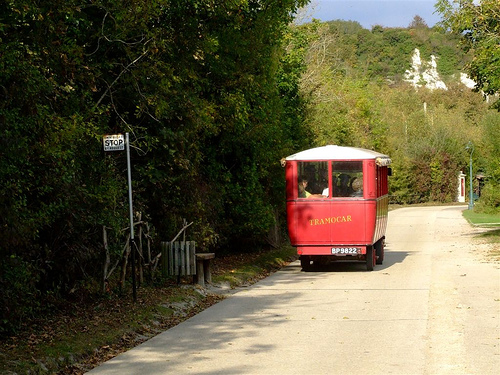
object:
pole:
[465, 136, 477, 213]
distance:
[273, 6, 498, 248]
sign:
[104, 131, 129, 152]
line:
[225, 291, 438, 333]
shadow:
[300, 247, 418, 278]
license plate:
[331, 245, 363, 255]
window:
[328, 161, 361, 197]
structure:
[405, 45, 425, 87]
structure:
[424, 51, 450, 92]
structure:
[451, 68, 491, 99]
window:
[292, 160, 328, 201]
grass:
[0, 246, 292, 371]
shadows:
[75, 262, 320, 375]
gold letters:
[304, 210, 354, 227]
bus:
[282, 144, 394, 271]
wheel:
[363, 242, 376, 271]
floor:
[85, 203, 500, 374]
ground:
[0, 206, 500, 375]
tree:
[0, 3, 270, 314]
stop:
[105, 140, 123, 145]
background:
[261, 0, 499, 211]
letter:
[309, 219, 314, 226]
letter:
[314, 219, 320, 226]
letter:
[320, 218, 325, 225]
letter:
[331, 217, 336, 224]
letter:
[345, 215, 352, 222]